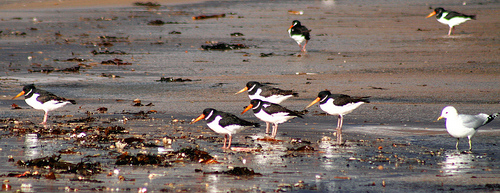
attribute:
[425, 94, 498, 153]
seagull — gray, white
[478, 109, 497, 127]
tail feathers — black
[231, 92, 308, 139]
bird — orange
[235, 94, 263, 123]
beak — bright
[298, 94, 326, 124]
bill — orange 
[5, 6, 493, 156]
seabirds — in a group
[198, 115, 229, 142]
breast — white 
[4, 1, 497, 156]
sand — brown, dark 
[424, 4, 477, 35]
bird — black, white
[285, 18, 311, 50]
bird — black, white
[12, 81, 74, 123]
bird — black, white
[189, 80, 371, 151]
birds — black, white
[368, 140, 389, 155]
orange object — smalll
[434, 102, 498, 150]
bird — white, gray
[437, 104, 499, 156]
bird — white 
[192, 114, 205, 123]
beak — skinny, orange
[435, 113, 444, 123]
beak — yellow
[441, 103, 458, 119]
head — white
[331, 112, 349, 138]
legs — short, pink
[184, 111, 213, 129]
beaks — orange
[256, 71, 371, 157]
bodies — black, white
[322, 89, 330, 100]
stripe — white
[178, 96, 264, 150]
streak — white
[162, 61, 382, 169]
birds — black, white, skimmer birds